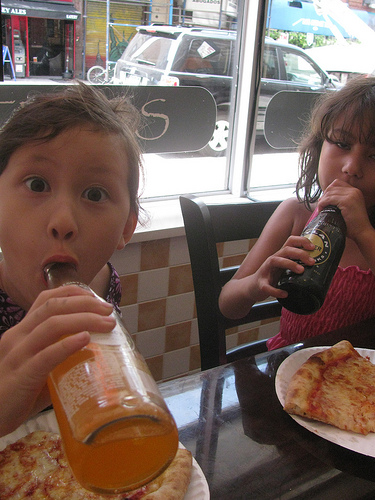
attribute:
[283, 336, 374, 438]
pizza — yellow, white, red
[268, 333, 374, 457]
plate — white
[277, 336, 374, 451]
pizza — yellow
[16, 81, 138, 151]
hair — messy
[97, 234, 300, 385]
wall — brown, white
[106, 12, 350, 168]
suv — black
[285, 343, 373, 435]
pizza — huge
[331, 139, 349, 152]
eye — sleepy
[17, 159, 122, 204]
eyes — wide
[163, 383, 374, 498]
table — wooden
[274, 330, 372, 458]
plate — circular, white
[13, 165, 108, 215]
eyes — open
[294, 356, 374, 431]
pizza — white, yellow, red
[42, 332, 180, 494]
juice — orange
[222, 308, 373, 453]
pizza — cheese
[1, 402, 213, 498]
plate — circular, white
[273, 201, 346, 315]
beer — brown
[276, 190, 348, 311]
bottle — dark brown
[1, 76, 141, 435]
girl — small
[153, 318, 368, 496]
table — dark brown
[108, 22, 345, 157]
car — parked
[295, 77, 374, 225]
girl — Drinking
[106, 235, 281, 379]
checkered wall — yellow, white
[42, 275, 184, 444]
bottle — clear, glass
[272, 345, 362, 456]
paper plate — white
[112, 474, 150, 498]
sauce — red, tomato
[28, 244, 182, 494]
pop — orange